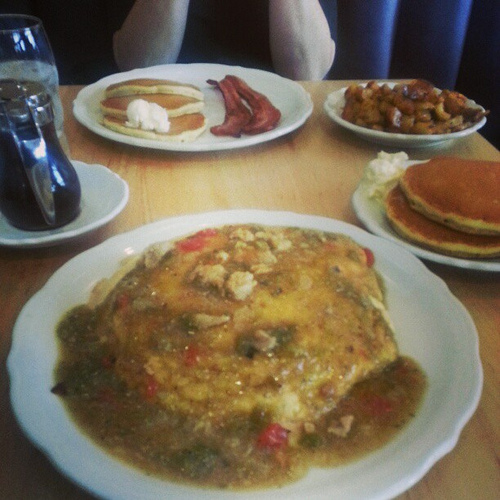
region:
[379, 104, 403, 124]
A piece of meat in a table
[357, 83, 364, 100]
A piece of meat in a table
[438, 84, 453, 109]
A piece of meat in a table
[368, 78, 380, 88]
A piece of meat in a table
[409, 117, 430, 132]
A piece of meat in a table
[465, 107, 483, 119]
A piece of meat in a table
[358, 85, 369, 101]
A piece of meat in a table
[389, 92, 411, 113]
A piece of meat in a table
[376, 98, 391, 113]
A piece of meat in a table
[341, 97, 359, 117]
A piece of meat in a table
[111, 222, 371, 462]
food on a plate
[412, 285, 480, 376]
white plate under food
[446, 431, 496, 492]
brown table next to plate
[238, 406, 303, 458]
red topping on food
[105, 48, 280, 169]
bacon and pancakes on plate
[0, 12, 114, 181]
drink on table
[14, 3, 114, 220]
drink filled half way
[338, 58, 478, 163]
bowl of food on table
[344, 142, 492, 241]
plate of pancakes on table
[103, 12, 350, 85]
person's arms next to food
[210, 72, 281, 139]
two slices of bacon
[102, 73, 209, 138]
stack of three pancakes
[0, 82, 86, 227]
glass pitcher of syrup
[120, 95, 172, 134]
butter pat on top of pancakes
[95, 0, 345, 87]
person's elbows resting on table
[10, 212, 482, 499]
white restaurant plate with scalloped rim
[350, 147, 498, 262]
pancakes with butter on the side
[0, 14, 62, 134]
clear glass with beverage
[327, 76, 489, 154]
small plate with hash browns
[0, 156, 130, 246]
small plate to catch syrup drippings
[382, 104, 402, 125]
a piece of meat on a plate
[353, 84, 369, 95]
a piece of meat on a plate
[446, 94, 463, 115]
a piece of meat on a plate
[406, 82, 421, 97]
a piece of meat on a plate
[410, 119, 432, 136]
a piece of meat on a plate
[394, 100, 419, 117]
a piece of meat on a plate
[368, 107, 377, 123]
a piece of meat on a plate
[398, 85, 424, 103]
a piece of meat on a plate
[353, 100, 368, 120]
a piece of meat on a plate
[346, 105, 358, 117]
a piece of meat on a plate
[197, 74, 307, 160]
Bacon on a plate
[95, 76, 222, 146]
Pancakes on a plate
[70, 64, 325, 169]
White plate with food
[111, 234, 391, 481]
Food on a plate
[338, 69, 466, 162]
Brown hash browns on a plate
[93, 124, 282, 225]
Brown table with food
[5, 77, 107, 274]
Syrup on a plate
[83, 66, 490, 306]
Breakfast on a table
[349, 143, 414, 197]
Butter on a plate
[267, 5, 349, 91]
Arm by a table